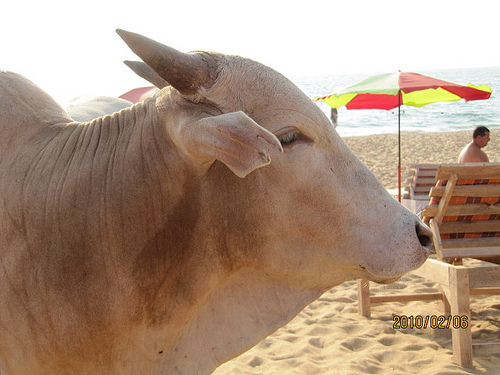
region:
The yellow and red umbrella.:
[322, 69, 495, 118]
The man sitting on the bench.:
[458, 118, 490, 163]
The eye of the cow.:
[276, 121, 313, 153]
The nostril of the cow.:
[401, 212, 438, 264]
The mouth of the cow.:
[358, 253, 411, 289]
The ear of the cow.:
[172, 97, 285, 179]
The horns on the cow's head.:
[118, 26, 218, 96]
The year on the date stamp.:
[386, 312, 426, 333]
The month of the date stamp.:
[427, 312, 447, 329]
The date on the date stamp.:
[453, 313, 468, 328]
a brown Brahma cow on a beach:
[0, 26, 432, 371]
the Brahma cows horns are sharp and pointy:
[115, 25, 210, 92]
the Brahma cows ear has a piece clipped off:
[191, 110, 278, 177]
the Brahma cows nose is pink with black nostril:
[415, 217, 430, 242]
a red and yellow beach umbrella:
[311, 67, 491, 104]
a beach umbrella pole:
[395, 92, 400, 202]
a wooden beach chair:
[365, 165, 496, 366]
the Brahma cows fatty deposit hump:
[0, 70, 70, 135]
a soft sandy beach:
[342, 130, 499, 187]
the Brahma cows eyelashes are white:
[276, 125, 313, 147]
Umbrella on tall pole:
[317, 31, 445, 221]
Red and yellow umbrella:
[343, 55, 447, 201]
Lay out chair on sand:
[391, 190, 461, 367]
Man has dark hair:
[441, 115, 497, 156]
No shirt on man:
[460, 140, 493, 175]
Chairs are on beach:
[365, 137, 473, 342]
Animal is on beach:
[36, 63, 363, 361]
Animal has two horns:
[108, 52, 218, 110]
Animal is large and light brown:
[76, 153, 262, 303]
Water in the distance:
[313, 66, 405, 240]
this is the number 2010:
[386, 313, 425, 333]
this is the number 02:
[430, 313, 447, 333]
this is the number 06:
[450, 312, 470, 334]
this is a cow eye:
[250, 90, 326, 178]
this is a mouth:
[318, 253, 426, 296]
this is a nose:
[388, 182, 447, 261]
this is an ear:
[181, 98, 289, 178]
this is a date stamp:
[388, 302, 484, 339]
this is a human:
[415, 97, 497, 218]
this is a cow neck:
[58, 71, 252, 373]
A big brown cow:
[15, 40, 423, 355]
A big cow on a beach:
[99, 64, 459, 348]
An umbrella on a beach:
[334, 67, 462, 183]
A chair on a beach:
[412, 157, 492, 322]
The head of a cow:
[138, 41, 446, 316]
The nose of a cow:
[382, 203, 439, 269]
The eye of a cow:
[264, 118, 320, 176]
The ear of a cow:
[180, 113, 290, 213]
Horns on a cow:
[122, 25, 232, 95]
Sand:
[306, 315, 400, 359]